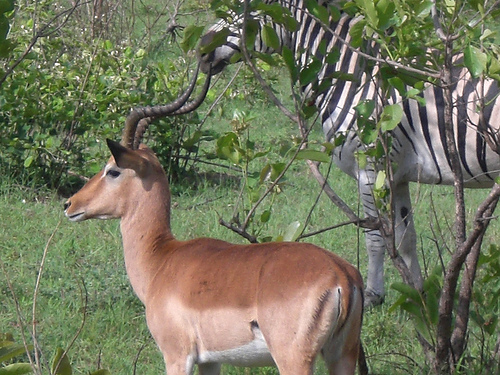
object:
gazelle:
[63, 61, 371, 374]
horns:
[118, 60, 213, 151]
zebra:
[195, 0, 500, 309]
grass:
[37, 299, 75, 330]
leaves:
[11, 75, 70, 101]